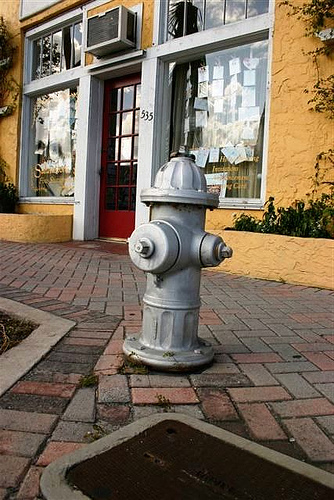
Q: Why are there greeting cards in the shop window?
A: Advertising.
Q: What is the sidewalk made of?
A: Brick.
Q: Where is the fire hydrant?
A: Sidewalk.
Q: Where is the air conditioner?
A: Over the door.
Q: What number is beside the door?
A: 5335.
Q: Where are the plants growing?
A: Flower boxes.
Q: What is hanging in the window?
A: Papers.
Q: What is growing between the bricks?
A: Weeds.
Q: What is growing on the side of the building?
A: Ivy.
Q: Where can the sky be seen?
A: Reflection in the windows.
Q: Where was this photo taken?
A: On a sidewalk.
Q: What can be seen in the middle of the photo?
A: Fire hydrant.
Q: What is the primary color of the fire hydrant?
A: Gray.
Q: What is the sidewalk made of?
A: Brick.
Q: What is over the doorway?
A: Air conditioner.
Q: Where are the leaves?
A: On the plant.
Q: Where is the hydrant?
A: On the ground.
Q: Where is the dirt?
A: On the ground.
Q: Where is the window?
A: On the building.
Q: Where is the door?
A: On the building.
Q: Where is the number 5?
A: On the building.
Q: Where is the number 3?
A: On the building.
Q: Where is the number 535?
A: On the building.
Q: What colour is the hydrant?
A: Silver.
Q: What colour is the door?
A: Red.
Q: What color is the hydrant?
A: Silver.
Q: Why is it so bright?
A: Sunny.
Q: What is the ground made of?
A: Bricks.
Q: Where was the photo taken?
A: Day time.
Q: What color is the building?
A: Yellow.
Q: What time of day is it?
A: Morning.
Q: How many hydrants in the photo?
A: One.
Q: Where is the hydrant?
A: The sidewalk.